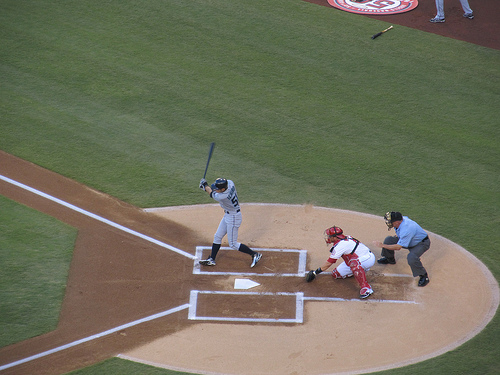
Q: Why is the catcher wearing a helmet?
A: To protect his head.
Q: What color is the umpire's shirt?
A: Blue.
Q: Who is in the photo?
A: Baseball players and an umpire.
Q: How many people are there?
A: Four.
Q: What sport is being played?
A: Baseball.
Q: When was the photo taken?
A: Daytime.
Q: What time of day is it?
A: Afternoon.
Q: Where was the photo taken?
A: At a baseball field.